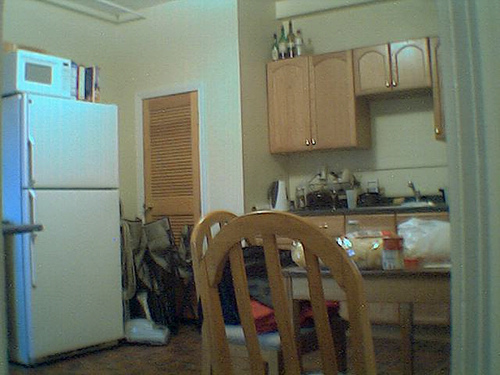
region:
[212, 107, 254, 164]
edge of a wall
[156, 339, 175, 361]
part of a floor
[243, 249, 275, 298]
part of a cjhir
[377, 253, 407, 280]
part of a table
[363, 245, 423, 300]
edge of a table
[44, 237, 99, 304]
part of a fridge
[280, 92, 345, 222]
part of a board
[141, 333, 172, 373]
part of a floor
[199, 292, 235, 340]
part of a chair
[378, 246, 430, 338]
part of a table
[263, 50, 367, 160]
Kitchen cupboard with doors closed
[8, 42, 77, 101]
White microwave oven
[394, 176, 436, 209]
Kitchen sink faucet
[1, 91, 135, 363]
White refrigerator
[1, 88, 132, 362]
Two door white refrigerator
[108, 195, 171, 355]
Upright vacuum cleaner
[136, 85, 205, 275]
Louvered wood door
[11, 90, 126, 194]
Refrigerator freezer door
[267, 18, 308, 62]
Bottles sitting on top of cupboard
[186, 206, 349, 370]
Wood chair with padded seat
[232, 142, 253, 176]
edge of a wall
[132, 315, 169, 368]
part of a floor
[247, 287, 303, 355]
part of a chair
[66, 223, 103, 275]
part of a fridge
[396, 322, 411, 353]
part of a stand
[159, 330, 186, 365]
part of a floor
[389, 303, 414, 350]
part of a stand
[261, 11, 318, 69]
alcoholic beverage bottle collection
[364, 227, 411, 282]
can of campbells soup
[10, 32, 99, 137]
small white microwave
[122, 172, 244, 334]
olive colored folding chair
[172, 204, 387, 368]
pair of wooden chairs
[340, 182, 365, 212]
plastic cup on counter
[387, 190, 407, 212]
sponge beside sink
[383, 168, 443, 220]
stainless steel sink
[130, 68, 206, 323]
small wooden door shielding water heater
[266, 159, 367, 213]
kitchen clutter next to sink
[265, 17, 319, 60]
Alcohol on top of cabinets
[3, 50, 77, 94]
Microwave oven on top of refrigerator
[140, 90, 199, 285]
Light wooden pantry door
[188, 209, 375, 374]
Light wooden chair back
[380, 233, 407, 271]
Can of food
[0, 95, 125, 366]
White refrigerator and freezer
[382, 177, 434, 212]
Sink built into counter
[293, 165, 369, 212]
Dishes in a drying rack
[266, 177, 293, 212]
Water boiling pitcher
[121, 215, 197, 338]
Fold up chairs